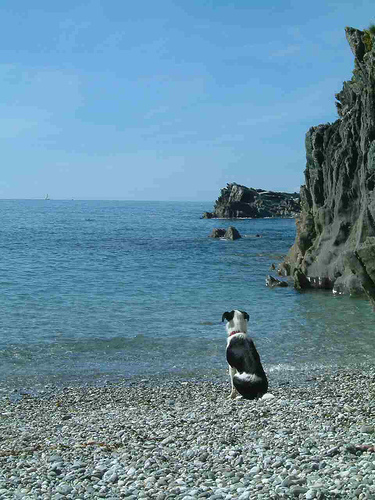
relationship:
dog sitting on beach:
[218, 305, 270, 403] [0, 397, 373, 497]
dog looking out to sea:
[218, 305, 270, 403] [2, 197, 199, 364]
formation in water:
[198, 180, 298, 220] [0, 201, 199, 375]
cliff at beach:
[275, 27, 373, 298] [0, 397, 373, 497]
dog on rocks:
[218, 305, 270, 403] [0, 364, 375, 499]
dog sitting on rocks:
[218, 305, 270, 403] [0, 364, 375, 499]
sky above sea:
[0, 0, 375, 203] [0, 197, 373, 382]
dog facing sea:
[218, 305, 270, 403] [0, 197, 373, 382]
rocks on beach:
[290, 482, 310, 494] [0, 367, 374, 498]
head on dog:
[219, 308, 251, 333] [218, 305, 270, 403]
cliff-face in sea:
[266, 24, 374, 297] [0, 197, 373, 382]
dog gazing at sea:
[218, 305, 270, 403] [0, 197, 373, 382]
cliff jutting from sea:
[275, 27, 373, 298] [0, 197, 373, 382]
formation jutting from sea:
[198, 180, 298, 220] [0, 197, 373, 382]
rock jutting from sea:
[208, 222, 243, 243] [0, 197, 373, 382]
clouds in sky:
[1, 2, 373, 204] [0, 0, 375, 203]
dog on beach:
[218, 305, 270, 403] [0, 367, 374, 498]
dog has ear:
[218, 305, 270, 403] [218, 309, 233, 323]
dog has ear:
[218, 305, 270, 403] [241, 309, 251, 321]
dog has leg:
[218, 305, 270, 403] [225, 364, 236, 398]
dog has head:
[218, 305, 270, 403] [221, 309, 250, 333]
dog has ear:
[218, 305, 270, 403] [241, 311, 251, 323]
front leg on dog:
[226, 364, 236, 397] [218, 305, 270, 403]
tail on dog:
[251, 388, 276, 400] [217, 306, 276, 402]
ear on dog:
[221, 310, 235, 320] [215, 304, 275, 407]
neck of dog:
[224, 323, 254, 339] [209, 304, 277, 408]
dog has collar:
[208, 300, 283, 411] [227, 327, 253, 342]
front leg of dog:
[226, 364, 236, 397] [218, 305, 270, 403]